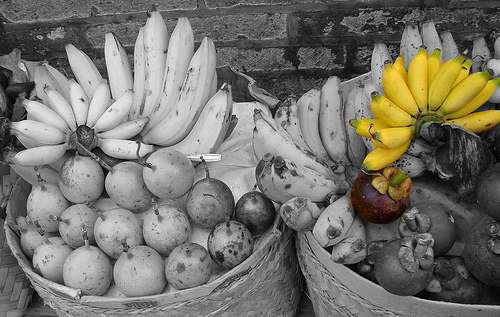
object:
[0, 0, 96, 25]
brick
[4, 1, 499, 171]
wall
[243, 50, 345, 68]
brick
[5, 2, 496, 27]
wall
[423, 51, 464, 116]
banana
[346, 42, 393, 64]
brick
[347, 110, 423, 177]
banana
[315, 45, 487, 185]
banana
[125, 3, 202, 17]
brick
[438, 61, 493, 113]
banana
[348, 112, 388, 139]
banana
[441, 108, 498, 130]
banana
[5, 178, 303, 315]
basket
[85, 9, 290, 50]
brick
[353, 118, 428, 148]
bananas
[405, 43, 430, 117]
banana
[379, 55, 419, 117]
banana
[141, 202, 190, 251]
fruits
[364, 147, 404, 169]
bananas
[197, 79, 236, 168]
bunches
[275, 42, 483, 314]
basket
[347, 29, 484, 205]
bunch